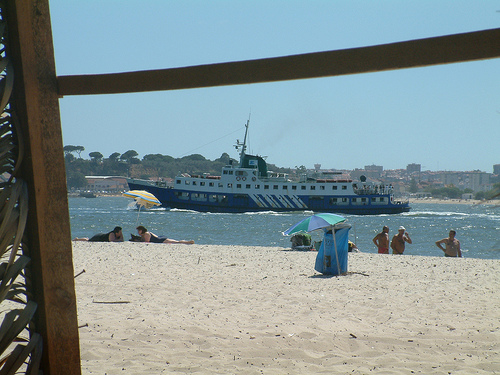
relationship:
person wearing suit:
[126, 221, 197, 251] [150, 229, 169, 243]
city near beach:
[351, 162, 499, 200] [408, 195, 499, 205]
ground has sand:
[172, 252, 365, 349] [78, 240, 490, 372]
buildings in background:
[380, 148, 489, 230] [59, 141, 499, 211]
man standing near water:
[426, 227, 468, 264] [70, 197, 499, 257]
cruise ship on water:
[113, 99, 416, 222] [412, 206, 498, 256]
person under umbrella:
[126, 221, 197, 251] [124, 188, 169, 243]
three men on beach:
[371, 220, 472, 263] [72, 238, 497, 373]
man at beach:
[369, 223, 393, 258] [0, 231, 496, 373]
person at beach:
[126, 221, 197, 251] [212, 257, 319, 344]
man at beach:
[426, 227, 468, 264] [0, 231, 496, 373]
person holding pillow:
[66, 221, 128, 248] [127, 230, 146, 242]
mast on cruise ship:
[236, 107, 257, 178] [113, 99, 416, 222]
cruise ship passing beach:
[113, 99, 416, 222] [72, 238, 497, 373]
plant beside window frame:
[1, 2, 40, 373] [3, 0, 499, 375]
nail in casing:
[75, 267, 86, 278] [1, 0, 82, 373]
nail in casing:
[77, 320, 89, 330] [1, 0, 82, 373]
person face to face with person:
[127, 224, 194, 246] [72, 225, 124, 244]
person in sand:
[127, 224, 194, 246] [1, 239, 497, 374]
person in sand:
[72, 225, 124, 244] [1, 239, 497, 374]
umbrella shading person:
[112, 184, 167, 243] [126, 221, 197, 251]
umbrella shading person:
[112, 184, 167, 243] [66, 221, 128, 248]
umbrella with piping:
[112, 184, 167, 243] [130, 191, 162, 207]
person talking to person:
[126, 221, 197, 251] [66, 221, 128, 248]